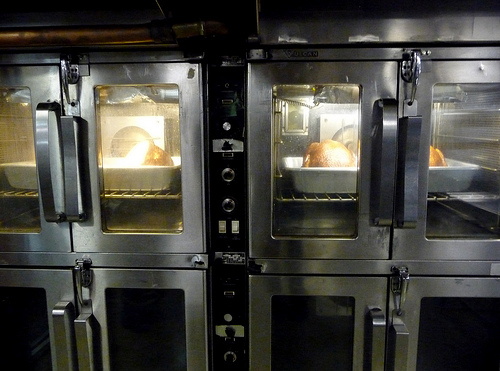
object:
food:
[301, 124, 442, 167]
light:
[114, 139, 149, 166]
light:
[95, 100, 176, 117]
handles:
[367, 317, 409, 368]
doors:
[264, 275, 385, 371]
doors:
[87, 267, 209, 371]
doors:
[3, 60, 78, 272]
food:
[129, 139, 173, 167]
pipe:
[0, 0, 500, 56]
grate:
[279, 186, 356, 207]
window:
[91, 84, 183, 237]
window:
[268, 84, 359, 241]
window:
[103, 286, 186, 371]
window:
[270, 296, 352, 371]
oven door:
[0, 60, 207, 252]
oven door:
[247, 49, 500, 260]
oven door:
[246, 273, 499, 371]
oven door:
[2, 267, 207, 371]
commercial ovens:
[0, 0, 500, 370]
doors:
[254, 60, 395, 263]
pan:
[279, 155, 478, 194]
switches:
[201, 48, 253, 369]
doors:
[57, 49, 203, 256]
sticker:
[267, 43, 497, 61]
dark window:
[270, 295, 356, 371]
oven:
[0, 32, 500, 370]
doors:
[392, 60, 494, 258]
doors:
[248, 276, 391, 371]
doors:
[0, 269, 76, 371]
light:
[313, 84, 359, 120]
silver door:
[0, 0, 500, 371]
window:
[276, 85, 356, 206]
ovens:
[4, 35, 500, 371]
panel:
[201, 60, 265, 371]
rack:
[0, 0, 500, 371]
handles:
[373, 97, 421, 225]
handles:
[48, 309, 100, 371]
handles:
[31, 107, 90, 226]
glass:
[270, 294, 353, 368]